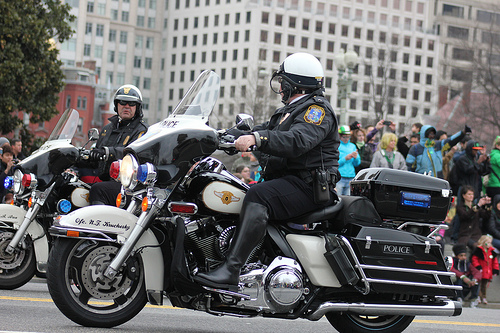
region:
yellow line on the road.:
[22, 290, 41, 304]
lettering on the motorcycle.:
[379, 246, 414, 253]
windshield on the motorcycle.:
[190, 74, 208, 106]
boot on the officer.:
[212, 217, 259, 300]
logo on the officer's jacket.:
[304, 107, 324, 129]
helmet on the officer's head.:
[283, 55, 317, 83]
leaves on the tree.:
[32, 76, 50, 92]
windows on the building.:
[76, 93, 85, 107]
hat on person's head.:
[455, 244, 467, 250]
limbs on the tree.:
[470, 43, 496, 99]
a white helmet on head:
[277, 48, 322, 83]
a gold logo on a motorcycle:
[214, 183, 241, 210]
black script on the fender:
[74, 215, 137, 232]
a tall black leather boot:
[191, 202, 263, 286]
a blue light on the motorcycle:
[401, 187, 427, 211]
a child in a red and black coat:
[474, 231, 498, 296]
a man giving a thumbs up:
[407, 125, 444, 171]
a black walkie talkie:
[309, 151, 334, 205]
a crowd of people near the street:
[341, 118, 498, 192]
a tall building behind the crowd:
[98, 0, 488, 127]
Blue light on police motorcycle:
[401, 190, 428, 207]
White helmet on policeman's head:
[271, 51, 327, 98]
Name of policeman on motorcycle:
[73, 217, 134, 230]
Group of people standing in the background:
[338, 119, 499, 304]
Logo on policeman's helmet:
[121, 85, 130, 92]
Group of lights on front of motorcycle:
[108, 155, 153, 184]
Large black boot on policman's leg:
[196, 200, 273, 291]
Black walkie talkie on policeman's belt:
[313, 145, 330, 202]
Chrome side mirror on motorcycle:
[218, 112, 255, 134]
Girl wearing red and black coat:
[471, 233, 498, 305]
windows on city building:
[97, 4, 471, 115]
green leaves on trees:
[2, 1, 74, 146]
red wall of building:
[37, 85, 95, 140]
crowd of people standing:
[348, 122, 496, 203]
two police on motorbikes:
[0, 52, 462, 331]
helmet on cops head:
[277, 51, 324, 95]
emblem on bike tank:
[209, 187, 244, 207]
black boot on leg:
[196, 199, 271, 287]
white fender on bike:
[57, 206, 164, 304]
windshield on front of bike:
[174, 68, 221, 120]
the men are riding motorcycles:
[0, 60, 462, 326]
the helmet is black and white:
[266, 52, 329, 92]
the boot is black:
[193, 199, 265, 294]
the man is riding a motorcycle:
[48, 51, 465, 328]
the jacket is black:
[253, 97, 345, 172]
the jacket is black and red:
[473, 244, 498, 285]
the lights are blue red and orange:
[104, 157, 203, 225]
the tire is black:
[43, 237, 153, 322]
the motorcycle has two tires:
[49, 219, 432, 331]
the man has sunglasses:
[119, 96, 141, 110]